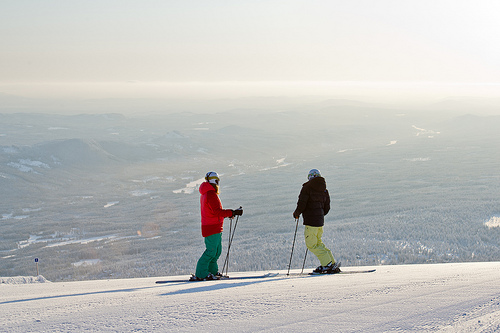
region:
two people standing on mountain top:
[132, 134, 380, 311]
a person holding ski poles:
[172, 152, 251, 296]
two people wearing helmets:
[189, 159, 334, 201]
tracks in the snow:
[185, 281, 442, 329]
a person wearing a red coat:
[200, 174, 232, 238]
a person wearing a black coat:
[297, 173, 338, 228]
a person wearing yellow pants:
[294, 207, 340, 277]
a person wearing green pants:
[197, 214, 236, 283]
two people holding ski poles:
[200, 162, 331, 289]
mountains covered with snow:
[7, 134, 156, 200]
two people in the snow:
[163, 127, 368, 272]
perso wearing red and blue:
[174, 151, 263, 282]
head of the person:
[194, 148, 231, 190]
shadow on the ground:
[170, 280, 217, 306]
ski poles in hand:
[220, 213, 247, 253]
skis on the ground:
[234, 264, 272, 295]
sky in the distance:
[218, 32, 341, 92]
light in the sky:
[372, 10, 481, 71]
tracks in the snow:
[376, 278, 463, 332]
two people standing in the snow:
[132, 115, 392, 300]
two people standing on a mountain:
[155, 137, 376, 310]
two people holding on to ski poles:
[177, 141, 363, 302]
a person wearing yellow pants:
[296, 169, 352, 281]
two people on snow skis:
[167, 136, 377, 286]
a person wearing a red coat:
[190, 170, 226, 246]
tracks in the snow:
[87, 268, 358, 331]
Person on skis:
[153, 270, 280, 287]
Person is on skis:
[154, 272, 279, 284]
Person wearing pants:
[191, 227, 223, 277]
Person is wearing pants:
[191, 227, 226, 276]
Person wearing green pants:
[193, 229, 225, 277]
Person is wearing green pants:
[196, 230, 226, 275]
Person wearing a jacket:
[194, 179, 235, 239]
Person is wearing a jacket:
[194, 180, 236, 238]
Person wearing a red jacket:
[197, 177, 233, 237]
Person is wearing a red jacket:
[195, 180, 240, 239]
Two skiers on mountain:
[156, 168, 380, 286]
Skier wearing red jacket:
[194, 181, 237, 237]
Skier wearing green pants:
[195, 238, 225, 279]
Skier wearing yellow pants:
[300, 224, 339, 266]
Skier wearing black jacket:
[293, 179, 329, 229]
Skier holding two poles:
[217, 204, 245, 278]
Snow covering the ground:
[0, 257, 498, 331]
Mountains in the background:
[0, 101, 498, 267]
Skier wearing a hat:
[202, 171, 221, 186]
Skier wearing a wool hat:
[303, 169, 323, 181]